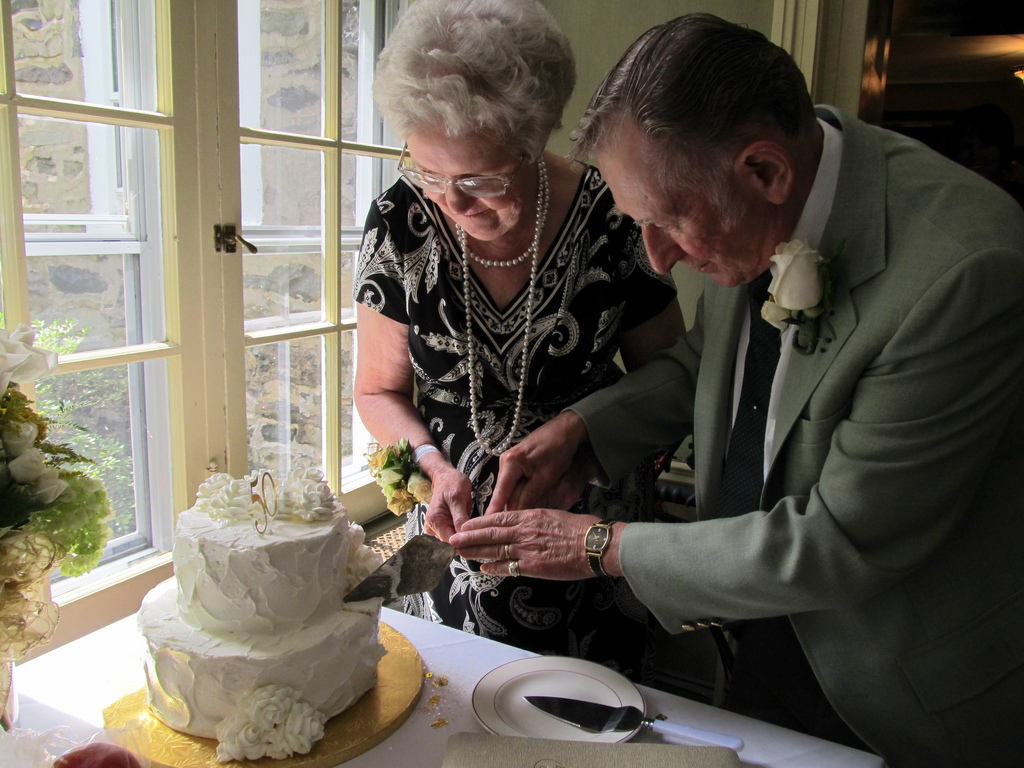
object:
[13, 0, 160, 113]
glass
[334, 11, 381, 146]
glass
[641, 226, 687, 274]
nose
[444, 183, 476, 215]
nose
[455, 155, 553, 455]
pearls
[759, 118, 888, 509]
lapel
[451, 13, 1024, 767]
man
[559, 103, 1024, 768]
suit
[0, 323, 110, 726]
bouquet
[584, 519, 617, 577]
watch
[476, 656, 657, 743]
cake spatula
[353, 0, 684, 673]
woman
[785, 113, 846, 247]
shirt collar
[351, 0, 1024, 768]
couple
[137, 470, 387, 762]
cake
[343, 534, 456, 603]
utensil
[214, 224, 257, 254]
window latch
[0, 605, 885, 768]
tablecloth